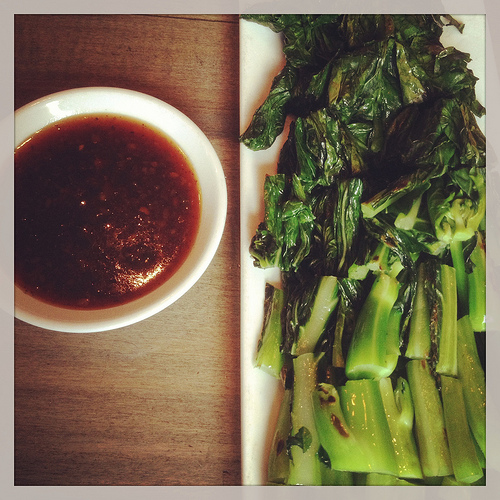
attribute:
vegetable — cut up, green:
[284, 350, 326, 483]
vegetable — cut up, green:
[310, 375, 400, 476]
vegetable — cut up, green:
[342, 270, 403, 377]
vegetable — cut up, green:
[252, 279, 285, 382]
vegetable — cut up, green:
[430, 260, 461, 376]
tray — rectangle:
[227, 27, 497, 400]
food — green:
[237, 12, 487, 484]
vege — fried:
[308, 377, 423, 479]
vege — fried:
[424, 259, 457, 377]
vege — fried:
[281, 272, 341, 362]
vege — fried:
[331, 173, 363, 277]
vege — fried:
[423, 161, 486, 246]